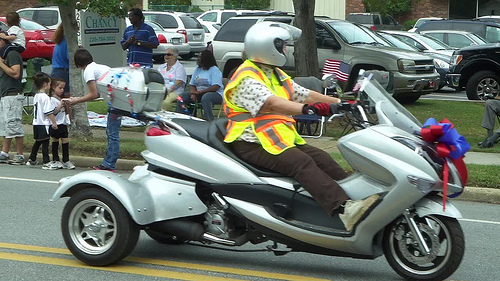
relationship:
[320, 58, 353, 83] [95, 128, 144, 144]
flag on sidewalk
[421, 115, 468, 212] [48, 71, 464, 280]
ribbon on vehicle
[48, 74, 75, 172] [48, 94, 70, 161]
girl in uniform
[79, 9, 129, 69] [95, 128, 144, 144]
sign on sidewalk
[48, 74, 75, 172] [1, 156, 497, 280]
girl on street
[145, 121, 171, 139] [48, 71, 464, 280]
taillight on vehicle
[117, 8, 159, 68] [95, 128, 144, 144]
man standing on sidewalk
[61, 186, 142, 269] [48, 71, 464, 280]
tire on vehicle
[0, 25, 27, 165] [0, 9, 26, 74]
father has child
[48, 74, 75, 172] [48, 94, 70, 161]
girl in her uniform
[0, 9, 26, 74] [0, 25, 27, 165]
child on her father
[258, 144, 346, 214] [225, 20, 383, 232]
lef of rider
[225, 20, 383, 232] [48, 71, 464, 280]
rider on vehicle